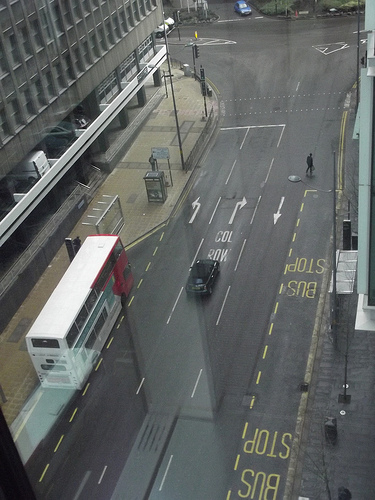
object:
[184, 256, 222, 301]
car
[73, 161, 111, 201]
stairway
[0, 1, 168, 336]
building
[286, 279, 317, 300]
word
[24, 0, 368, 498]
road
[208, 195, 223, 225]
lines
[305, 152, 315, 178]
pedestrian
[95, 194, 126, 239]
bus stop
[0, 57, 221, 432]
sidewalk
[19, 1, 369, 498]
street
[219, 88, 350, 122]
crosswalk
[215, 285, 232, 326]
markings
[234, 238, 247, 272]
markings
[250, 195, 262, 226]
markings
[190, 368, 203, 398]
markings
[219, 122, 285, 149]
marking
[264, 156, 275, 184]
marking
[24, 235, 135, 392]
bus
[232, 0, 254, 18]
car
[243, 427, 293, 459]
word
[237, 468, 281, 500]
word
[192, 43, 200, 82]
stoplight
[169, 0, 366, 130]
intersection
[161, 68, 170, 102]
post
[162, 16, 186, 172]
street light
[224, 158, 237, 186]
lines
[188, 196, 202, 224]
arrow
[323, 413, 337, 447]
garbage can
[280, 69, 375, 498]
sidewalk